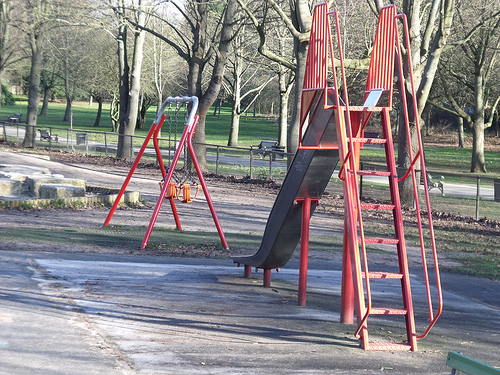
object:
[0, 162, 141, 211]
structure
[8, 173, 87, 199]
stone carving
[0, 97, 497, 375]
ground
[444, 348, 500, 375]
top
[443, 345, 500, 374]
bench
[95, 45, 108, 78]
trees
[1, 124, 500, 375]
playground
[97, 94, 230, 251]
swing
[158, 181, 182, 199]
seats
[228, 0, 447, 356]
slide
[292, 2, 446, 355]
ladder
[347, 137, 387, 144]
rung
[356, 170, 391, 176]
rung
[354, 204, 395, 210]
rung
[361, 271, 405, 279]
rung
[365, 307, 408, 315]
rung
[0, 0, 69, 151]
tree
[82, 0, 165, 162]
tree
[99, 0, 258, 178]
tree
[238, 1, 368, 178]
tree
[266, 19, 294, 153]
tree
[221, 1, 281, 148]
tree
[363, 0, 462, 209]
tree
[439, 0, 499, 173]
tree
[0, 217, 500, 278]
astro turf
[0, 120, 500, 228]
fence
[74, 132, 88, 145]
waste basket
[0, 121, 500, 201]
path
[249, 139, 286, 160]
bench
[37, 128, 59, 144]
bench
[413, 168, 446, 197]
bench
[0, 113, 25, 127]
bench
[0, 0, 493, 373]
park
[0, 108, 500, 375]
public park